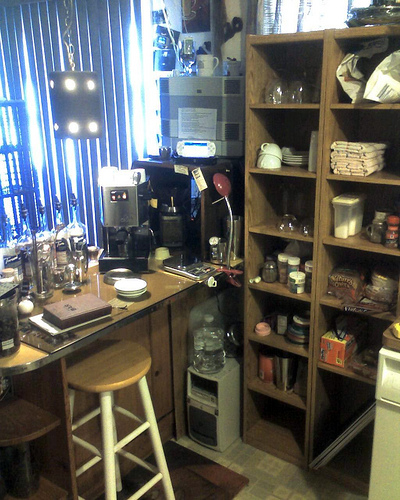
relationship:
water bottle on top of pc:
[187, 304, 231, 371] [178, 360, 258, 448]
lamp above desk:
[26, 56, 125, 150] [1, 262, 206, 484]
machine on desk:
[77, 162, 157, 271] [1, 253, 243, 485]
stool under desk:
[54, 342, 167, 498] [1, 253, 243, 485]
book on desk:
[43, 290, 113, 320] [1, 253, 243, 485]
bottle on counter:
[44, 232, 80, 284] [26, 262, 180, 320]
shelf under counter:
[1, 403, 62, 495] [26, 262, 180, 320]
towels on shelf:
[324, 123, 382, 179] [248, 19, 395, 482]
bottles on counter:
[17, 236, 90, 287] [26, 262, 180, 320]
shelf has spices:
[248, 19, 395, 482] [259, 257, 287, 278]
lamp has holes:
[26, 56, 125, 150] [47, 119, 109, 136]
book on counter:
[43, 290, 113, 320] [26, 262, 180, 320]